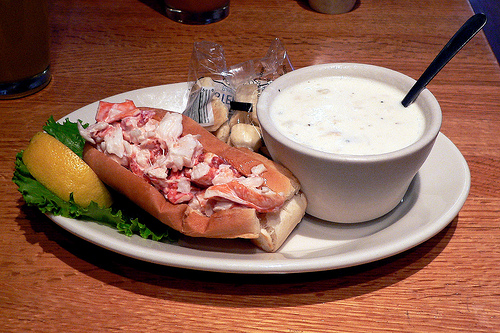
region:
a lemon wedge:
[23, 123, 115, 215]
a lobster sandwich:
[85, 98, 303, 247]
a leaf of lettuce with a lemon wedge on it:
[12, 98, 82, 230]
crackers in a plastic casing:
[190, 27, 262, 145]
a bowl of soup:
[259, 50, 463, 228]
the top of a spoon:
[409, 4, 489, 111]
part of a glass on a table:
[2, 0, 56, 99]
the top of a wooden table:
[350, 286, 495, 331]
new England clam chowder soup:
[304, 84, 388, 136]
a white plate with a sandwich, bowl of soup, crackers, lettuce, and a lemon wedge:
[13, 64, 499, 289]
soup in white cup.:
[309, 98, 372, 130]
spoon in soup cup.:
[414, 37, 468, 92]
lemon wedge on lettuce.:
[30, 142, 77, 187]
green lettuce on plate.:
[36, 197, 68, 222]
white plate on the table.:
[299, 235, 377, 273]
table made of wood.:
[384, 292, 474, 322]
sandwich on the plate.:
[137, 127, 218, 199]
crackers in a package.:
[195, 71, 250, 125]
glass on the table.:
[5, 17, 36, 88]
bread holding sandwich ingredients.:
[190, 222, 251, 232]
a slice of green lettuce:
[11, 97, 173, 271]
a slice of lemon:
[4, 115, 141, 233]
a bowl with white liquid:
[223, 34, 455, 239]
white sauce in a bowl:
[239, 34, 452, 240]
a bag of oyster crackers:
[176, 37, 313, 179]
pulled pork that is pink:
[100, 100, 281, 235]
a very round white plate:
[16, 43, 493, 302]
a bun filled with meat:
[85, 92, 321, 264]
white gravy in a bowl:
[241, 28, 465, 245]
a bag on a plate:
[157, 19, 334, 186]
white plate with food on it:
[33, 35, 472, 301]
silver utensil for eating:
[253, 9, 488, 200]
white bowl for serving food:
[253, 36, 441, 223]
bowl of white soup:
[254, 66, 465, 215]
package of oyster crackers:
[162, 32, 305, 173]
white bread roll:
[64, 91, 349, 291]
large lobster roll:
[78, 69, 310, 257]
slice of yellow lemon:
[0, 126, 135, 253]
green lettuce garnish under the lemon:
[23, 93, 170, 278]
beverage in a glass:
[3, 9, 83, 131]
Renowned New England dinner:
[20, 45, 473, 272]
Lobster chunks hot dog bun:
[102, 105, 291, 243]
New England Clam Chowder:
[268, 64, 435, 219]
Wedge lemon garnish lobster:
[17, 113, 126, 224]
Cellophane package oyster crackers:
[187, 22, 294, 147]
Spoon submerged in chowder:
[366, 15, 469, 188]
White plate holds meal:
[29, 76, 481, 285]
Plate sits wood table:
[18, 73, 482, 326]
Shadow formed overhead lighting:
[20, 220, 490, 304]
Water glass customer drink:
[0, 5, 89, 95]